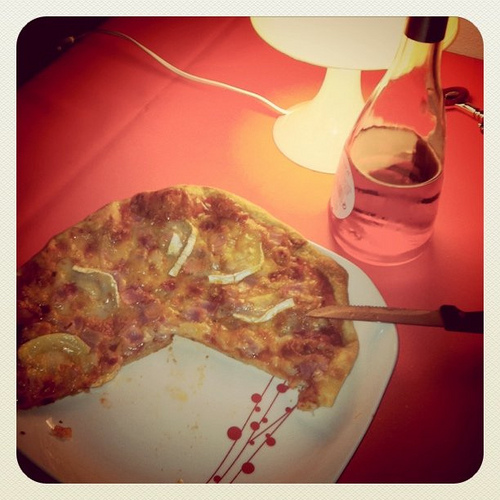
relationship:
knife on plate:
[304, 305, 485, 335] [17, 413, 375, 481]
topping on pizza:
[17, 332, 89, 357] [22, 183, 359, 409]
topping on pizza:
[232, 297, 295, 325] [22, 183, 359, 409]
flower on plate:
[212, 382, 298, 483] [17, 413, 375, 481]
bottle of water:
[331, 17, 449, 267] [331, 126, 441, 264]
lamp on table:
[248, 17, 336, 174] [23, 20, 250, 182]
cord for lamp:
[91, 27, 287, 115] [248, 17, 336, 174]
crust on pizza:
[207, 190, 321, 266] [22, 183, 359, 409]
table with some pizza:
[23, 20, 250, 182] [22, 183, 359, 409]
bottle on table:
[331, 17, 449, 267] [23, 20, 250, 182]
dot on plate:
[227, 424, 244, 443] [17, 413, 375, 481]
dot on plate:
[250, 391, 262, 404] [17, 413, 375, 481]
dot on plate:
[276, 382, 288, 394] [17, 413, 375, 481]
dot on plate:
[240, 460, 256, 477] [17, 413, 375, 481]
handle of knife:
[438, 305, 485, 333] [304, 305, 485, 335]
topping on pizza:
[170, 217, 198, 279] [22, 183, 359, 409]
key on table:
[443, 86, 487, 129] [23, 20, 250, 182]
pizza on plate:
[22, 183, 359, 409] [17, 413, 375, 481]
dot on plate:
[267, 437, 276, 447] [17, 413, 375, 481]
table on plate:
[23, 20, 250, 182] [17, 413, 375, 481]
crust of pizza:
[207, 190, 321, 266] [22, 183, 359, 409]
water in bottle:
[331, 126, 441, 264] [331, 17, 449, 267]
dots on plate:
[226, 393, 276, 481] [17, 413, 375, 481]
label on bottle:
[331, 150, 355, 218] [331, 17, 449, 267]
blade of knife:
[306, 305, 442, 326] [304, 305, 485, 335]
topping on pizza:
[77, 263, 121, 303] [22, 183, 359, 409]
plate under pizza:
[17, 413, 375, 481] [22, 183, 359, 409]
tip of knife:
[305, 307, 339, 321] [304, 305, 485, 335]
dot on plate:
[283, 405, 292, 415] [17, 413, 375, 481]